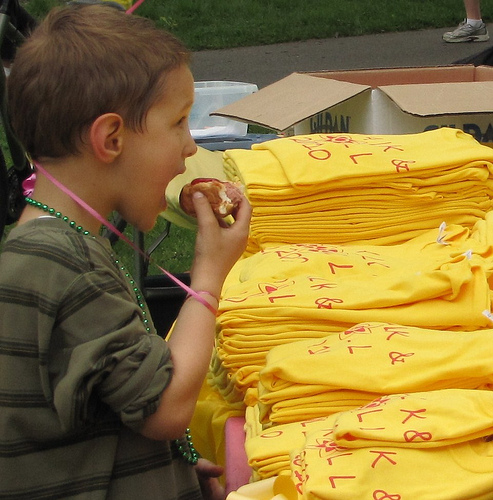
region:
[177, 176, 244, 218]
half-eaten hot dog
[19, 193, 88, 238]
green mardi gras beads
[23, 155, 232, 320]
pink gift ribbon around boy's wrist and neck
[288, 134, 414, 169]
red writing on yellow shirts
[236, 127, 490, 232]
stack of yellow shirts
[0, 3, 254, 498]
boy eating hot dog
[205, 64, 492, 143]
empty card board box on table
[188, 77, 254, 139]
transluscent plastic tub with papers inside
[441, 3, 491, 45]
sneaker of person walking into frame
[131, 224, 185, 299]
elbow joint of table leg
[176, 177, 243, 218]
half eaten hot dog with ketchup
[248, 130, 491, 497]
four piles of folded red and yellow t-shirts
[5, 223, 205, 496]
green and black child's long sleeve shirt with rolled up sleeves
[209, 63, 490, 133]
open cardboard box with blue writing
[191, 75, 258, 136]
clear plastic container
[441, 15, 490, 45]
white and grey sneaker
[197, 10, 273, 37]
patch of green grass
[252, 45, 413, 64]
grey cement sidewalk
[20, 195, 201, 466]
green plastic beads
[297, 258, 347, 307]
red writing on front of yellow folded t-shirt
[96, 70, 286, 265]
boy is eating a hot dog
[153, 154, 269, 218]
hotdog has catsup on it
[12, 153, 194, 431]
boy is wearing green beads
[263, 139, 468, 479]
piles of shirts are yellow with red print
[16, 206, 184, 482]
boy's shirt is green with dark stripes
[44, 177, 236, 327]
a pink ribbon around boy's wrist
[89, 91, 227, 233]
boy's mouth is open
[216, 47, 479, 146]
cardboard box is open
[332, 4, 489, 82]
another person stands on the sidewalk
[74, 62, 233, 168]
the boy's eyes are open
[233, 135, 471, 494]
piles of yellow shirts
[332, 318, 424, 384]
the shirts have red letters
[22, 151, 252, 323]
the boy is wearing a pink ribbon around his neck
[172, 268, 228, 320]
the ribbon is wrapped around his wrist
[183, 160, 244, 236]
the boy is eating a hot dog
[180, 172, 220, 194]
ketchup on the hot dog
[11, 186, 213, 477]
the boy is wearing shiny green beads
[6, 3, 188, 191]
the boy has brown hair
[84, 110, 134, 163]
the boy's ear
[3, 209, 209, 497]
the boy is wearing a green and black striped shirt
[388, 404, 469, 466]
orange markings on yellow shirt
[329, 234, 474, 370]
stack of yellow tee shirts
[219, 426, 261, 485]
pink edge of table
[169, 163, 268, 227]
hot dog in boy's hand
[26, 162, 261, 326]
pink string around boy's neck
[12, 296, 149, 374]
green and black shirt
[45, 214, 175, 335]
shiny green beads around boy's head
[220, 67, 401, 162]
lid of white card board box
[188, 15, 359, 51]
long patch of green grass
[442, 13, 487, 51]
gray and white sneakers